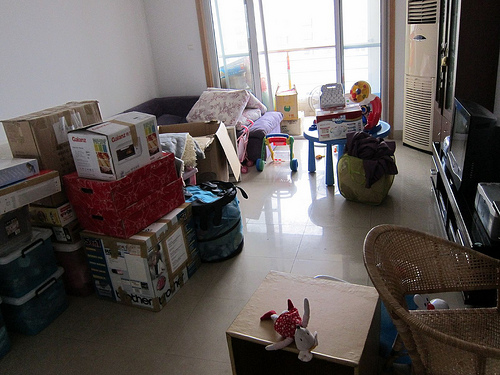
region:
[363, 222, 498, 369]
most of a wicker chair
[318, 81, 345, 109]
an insulated lunch bag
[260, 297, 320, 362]
a child's doll in the shape of a mouse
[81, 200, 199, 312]
large box with strips of brown tape on it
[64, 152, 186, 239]
two large rectangular red and gold colored boxes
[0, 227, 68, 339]
two large stacked bins with white lids and black handles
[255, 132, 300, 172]
a child's toy on the ground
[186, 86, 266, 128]
large cushions stacked on each other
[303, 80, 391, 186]
items piled on a round-topped blue table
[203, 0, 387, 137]
bright light coming in through large windows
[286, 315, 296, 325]
red and white shirt on doll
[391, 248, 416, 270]
back of brown straw chair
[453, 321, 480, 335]
seat of brown straw chair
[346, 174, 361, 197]
green hamper in room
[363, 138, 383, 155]
clothes on top of hamper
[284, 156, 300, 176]
right wheel on walker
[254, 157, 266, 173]
left wheel on walker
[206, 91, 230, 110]
white and brown cushion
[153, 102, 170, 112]
blue sofa in room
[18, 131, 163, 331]
boxes and bins in room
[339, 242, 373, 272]
part of a floor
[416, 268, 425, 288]
part of a chair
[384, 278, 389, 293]
edge of a chair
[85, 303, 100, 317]
part of a floor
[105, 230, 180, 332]
side of a box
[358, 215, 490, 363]
large wicker chair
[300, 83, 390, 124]
many toys on a table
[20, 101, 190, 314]
multiple boxes on the floor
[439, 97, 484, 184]
black tv on a stand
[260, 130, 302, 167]
small childs walker toy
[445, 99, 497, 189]
TV on a stand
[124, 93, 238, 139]
purple couch in the corner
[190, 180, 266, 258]
blue and black laundry hamper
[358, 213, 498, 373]
this is a chair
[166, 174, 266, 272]
this is a basket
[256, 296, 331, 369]
this is a toy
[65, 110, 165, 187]
this is a basket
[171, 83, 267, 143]
this is a pillow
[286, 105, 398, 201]
this is a table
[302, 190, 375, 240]
this is a tile